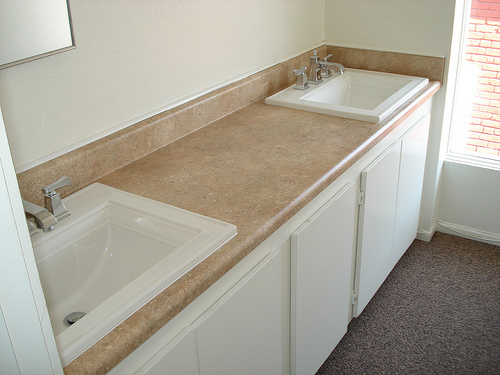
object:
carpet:
[311, 232, 499, 374]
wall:
[1, 0, 456, 244]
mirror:
[2, 0, 82, 79]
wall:
[462, 2, 500, 167]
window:
[434, 0, 500, 168]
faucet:
[289, 50, 352, 92]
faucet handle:
[322, 54, 337, 62]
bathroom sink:
[21, 181, 239, 368]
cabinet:
[352, 110, 433, 319]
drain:
[61, 309, 83, 324]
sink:
[263, 67, 428, 123]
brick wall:
[462, 0, 500, 156]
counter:
[102, 100, 379, 227]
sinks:
[21, 177, 242, 364]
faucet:
[18, 171, 78, 237]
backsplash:
[0, 39, 445, 373]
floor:
[307, 222, 500, 375]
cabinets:
[194, 174, 365, 373]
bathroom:
[2, 2, 500, 374]